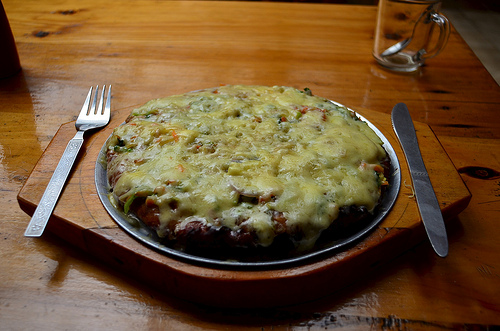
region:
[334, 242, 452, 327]
table is wooden and rustic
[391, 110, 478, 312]
table is wooden and rustic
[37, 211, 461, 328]
table is wooden and rustic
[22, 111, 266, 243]
table is wooden and rustic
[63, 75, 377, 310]
table is wooden and rustic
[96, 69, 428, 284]
this appears to be a pizza or a frittata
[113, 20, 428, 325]
it has a lot of cheese on it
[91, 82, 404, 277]
it is served on a pizza pan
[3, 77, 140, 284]
the fork is silver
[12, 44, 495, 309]
the serving board is wood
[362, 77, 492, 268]
the knife is silver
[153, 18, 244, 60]
the table is made from wood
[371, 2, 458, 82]
the glass has a spoon in it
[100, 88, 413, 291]
the food looks to have tomatoes in it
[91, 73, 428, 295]
what a delicious lunch this would be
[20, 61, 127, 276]
fork with four tines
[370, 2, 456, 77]
cu with spoon in it.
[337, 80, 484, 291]
knife with plate of food to left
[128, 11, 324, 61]
wood table with varnish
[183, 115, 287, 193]
melted chees on top of pizza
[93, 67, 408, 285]
cheese pizza on a round tray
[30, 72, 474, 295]
plate of food with cutlery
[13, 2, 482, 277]
pizza with cutlery with cup.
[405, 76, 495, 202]
knots in wood table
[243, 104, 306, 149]
goopy melted cheese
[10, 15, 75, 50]
small black spot on table surface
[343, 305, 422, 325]
small black line on the surface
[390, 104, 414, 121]
edge of silver knife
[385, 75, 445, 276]
large silver knife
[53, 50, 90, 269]
long silver fork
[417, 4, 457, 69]
handle of clear beer mug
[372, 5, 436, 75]
silver spoon in mug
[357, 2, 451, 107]
clear mug on table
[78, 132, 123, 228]
silver edge of metal plate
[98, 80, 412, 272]
silver plate filled with cheese covered food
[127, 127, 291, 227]
patty has green cheese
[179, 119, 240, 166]
patty has green cheese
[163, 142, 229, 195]
patty has green cheese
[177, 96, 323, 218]
patty has green cheese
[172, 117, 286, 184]
patty has green cheese